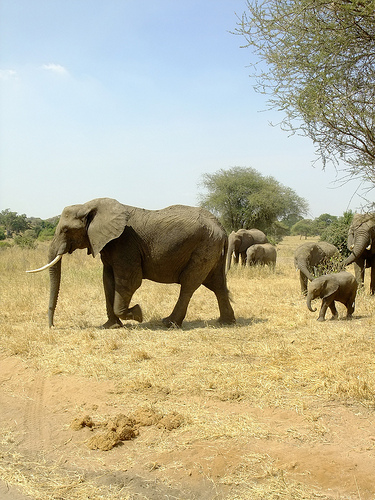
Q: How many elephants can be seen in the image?
A: Six.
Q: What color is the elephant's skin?
A: Gray.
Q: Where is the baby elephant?
A: Middle right of image.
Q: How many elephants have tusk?
A: Two.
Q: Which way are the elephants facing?
A: Left.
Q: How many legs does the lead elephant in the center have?
A: Four.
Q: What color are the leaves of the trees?
A: Green.